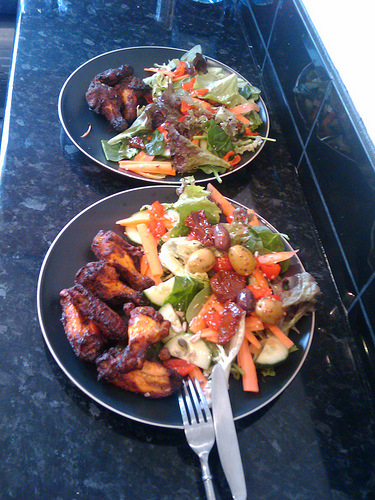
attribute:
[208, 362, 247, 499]
knife — silver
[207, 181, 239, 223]
carrot — coming off